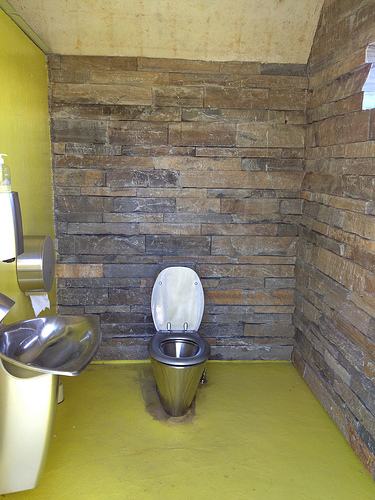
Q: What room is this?
A: It is a bathroom.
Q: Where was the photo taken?
A: It was taken at the bathroom.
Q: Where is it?
A: This is at the bathroom.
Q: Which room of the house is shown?
A: It is a bathroom.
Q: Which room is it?
A: It is a bathroom.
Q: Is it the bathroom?
A: Yes, it is the bathroom.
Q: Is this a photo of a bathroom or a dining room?
A: It is showing a bathroom.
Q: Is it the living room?
A: No, it is the bathroom.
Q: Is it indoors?
A: Yes, it is indoors.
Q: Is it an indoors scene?
A: Yes, it is indoors.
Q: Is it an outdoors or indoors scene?
A: It is indoors.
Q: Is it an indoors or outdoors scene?
A: It is indoors.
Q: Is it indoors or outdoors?
A: It is indoors.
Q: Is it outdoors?
A: No, it is indoors.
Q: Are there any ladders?
A: No, there are no ladders.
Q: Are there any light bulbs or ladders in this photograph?
A: No, there are no ladders or light bulbs.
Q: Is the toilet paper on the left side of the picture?
A: Yes, the toilet paper is on the left of the image.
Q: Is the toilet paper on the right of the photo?
A: No, the toilet paper is on the left of the image.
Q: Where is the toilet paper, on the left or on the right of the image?
A: The toilet paper is on the left of the image.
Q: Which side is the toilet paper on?
A: The toilet paper is on the left of the image.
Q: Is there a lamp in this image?
A: No, there are no lamps.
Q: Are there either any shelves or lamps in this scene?
A: No, there are no lamps or shelves.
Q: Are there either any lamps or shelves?
A: No, there are no lamps or shelves.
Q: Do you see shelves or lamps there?
A: No, there are no lamps or shelves.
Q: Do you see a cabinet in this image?
A: No, there are no cabinets.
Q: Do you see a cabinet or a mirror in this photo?
A: No, there are no cabinets or mirrors.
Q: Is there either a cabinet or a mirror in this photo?
A: No, there are no cabinets or mirrors.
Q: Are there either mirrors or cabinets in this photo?
A: No, there are no cabinets or mirrors.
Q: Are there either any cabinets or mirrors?
A: No, there are no cabinets or mirrors.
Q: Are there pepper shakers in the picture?
A: No, there are no pepper shakers.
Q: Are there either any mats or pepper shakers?
A: No, there are no pepper shakers or mats.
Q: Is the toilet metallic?
A: Yes, the toilet is metallic.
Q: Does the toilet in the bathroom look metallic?
A: Yes, the toilet is metallic.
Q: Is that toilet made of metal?
A: Yes, the toilet is made of metal.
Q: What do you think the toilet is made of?
A: The toilet is made of metal.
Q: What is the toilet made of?
A: The toilet is made of metal.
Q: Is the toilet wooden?
A: No, the toilet is metallic.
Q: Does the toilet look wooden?
A: No, the toilet is metallic.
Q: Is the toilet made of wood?
A: No, the toilet is made of metal.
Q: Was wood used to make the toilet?
A: No, the toilet is made of metal.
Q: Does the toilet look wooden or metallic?
A: The toilet is metallic.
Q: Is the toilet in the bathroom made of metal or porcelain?
A: The toilet is made of metal.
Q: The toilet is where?
A: The toilet is in the bathroom.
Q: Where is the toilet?
A: The toilet is in the bathroom.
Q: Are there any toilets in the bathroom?
A: Yes, there is a toilet in the bathroom.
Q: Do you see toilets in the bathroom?
A: Yes, there is a toilet in the bathroom.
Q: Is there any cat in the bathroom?
A: No, there is a toilet in the bathroom.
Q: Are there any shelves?
A: No, there are no shelves.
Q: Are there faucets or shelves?
A: No, there are no shelves or faucets.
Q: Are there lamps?
A: No, there are no lamps.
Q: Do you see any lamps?
A: No, there are no lamps.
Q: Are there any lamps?
A: No, there are no lamps.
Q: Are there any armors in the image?
A: No, there are no armors.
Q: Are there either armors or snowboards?
A: No, there are no armors or snowboards.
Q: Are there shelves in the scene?
A: No, there are no shelves.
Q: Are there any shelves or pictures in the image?
A: No, there are no shelves or pictures.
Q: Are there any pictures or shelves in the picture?
A: No, there are no shelves or pictures.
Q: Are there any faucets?
A: No, there are no faucets.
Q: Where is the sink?
A: The sink is in the bathroom.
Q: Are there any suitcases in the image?
A: No, there are no suitcases.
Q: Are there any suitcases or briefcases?
A: No, there are no suitcases or briefcases.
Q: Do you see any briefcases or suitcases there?
A: No, there are no suitcases or briefcases.